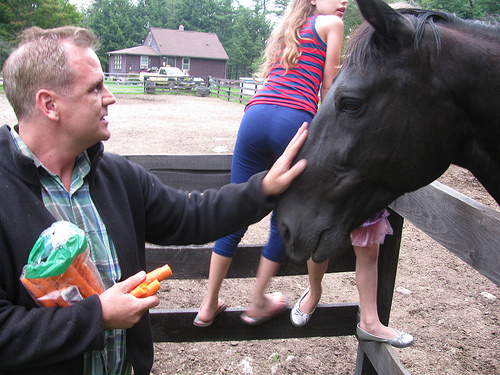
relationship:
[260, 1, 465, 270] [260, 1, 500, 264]
head of horse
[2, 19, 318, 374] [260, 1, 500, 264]
man petting horse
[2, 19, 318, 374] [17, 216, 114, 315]
man holding bag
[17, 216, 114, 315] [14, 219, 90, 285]
bag with top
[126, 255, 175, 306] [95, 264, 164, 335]
carrots in hand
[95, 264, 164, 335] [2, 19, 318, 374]
hand of man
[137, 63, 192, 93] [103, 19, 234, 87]
truck in front of house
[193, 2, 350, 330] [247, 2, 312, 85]
girl with hair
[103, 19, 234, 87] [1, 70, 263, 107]
house behind fence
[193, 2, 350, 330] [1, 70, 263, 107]
girl on fence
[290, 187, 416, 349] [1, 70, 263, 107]
girl on fence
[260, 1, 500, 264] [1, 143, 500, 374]
horse by fence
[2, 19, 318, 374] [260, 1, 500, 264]
man touching horse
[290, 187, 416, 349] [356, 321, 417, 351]
girl wearing shoes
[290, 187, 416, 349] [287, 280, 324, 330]
girl wearing shoes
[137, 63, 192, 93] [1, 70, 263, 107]
truck by fence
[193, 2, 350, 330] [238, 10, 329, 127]
girl wearing top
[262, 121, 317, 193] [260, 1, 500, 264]
hand on horse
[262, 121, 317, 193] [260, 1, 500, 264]
hand strokes horse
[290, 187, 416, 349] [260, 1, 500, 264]
girl behind horse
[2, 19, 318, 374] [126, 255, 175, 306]
man holding carrots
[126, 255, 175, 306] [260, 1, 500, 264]
carrots for horse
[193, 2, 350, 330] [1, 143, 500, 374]
girl on fence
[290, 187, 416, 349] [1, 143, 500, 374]
girl on fence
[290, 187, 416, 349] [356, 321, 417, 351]
girl has shoes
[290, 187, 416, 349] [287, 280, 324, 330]
girl has shoes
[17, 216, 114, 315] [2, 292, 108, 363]
bag on arm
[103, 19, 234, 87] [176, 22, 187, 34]
house has chimney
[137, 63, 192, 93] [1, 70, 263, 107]
truck next to fence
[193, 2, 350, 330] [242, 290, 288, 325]
girl wearing flip flops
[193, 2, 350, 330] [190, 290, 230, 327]
girl wearing flip flops